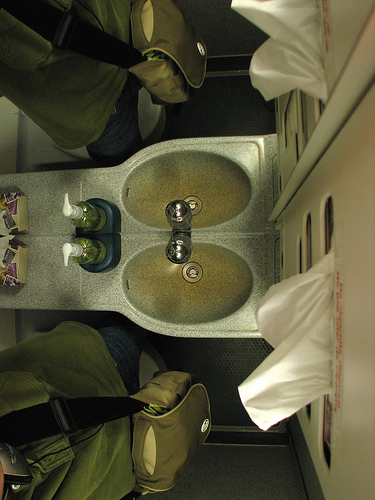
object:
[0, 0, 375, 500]
bathroom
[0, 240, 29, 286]
box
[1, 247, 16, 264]
paper towels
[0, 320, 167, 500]
person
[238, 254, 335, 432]
tissue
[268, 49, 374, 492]
container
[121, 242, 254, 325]
sink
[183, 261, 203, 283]
drain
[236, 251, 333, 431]
towel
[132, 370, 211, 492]
pack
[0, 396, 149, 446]
strap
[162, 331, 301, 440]
floor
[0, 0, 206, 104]
backpack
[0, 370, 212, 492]
backpack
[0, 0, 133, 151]
green shirt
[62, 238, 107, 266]
bottle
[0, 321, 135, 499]
shirt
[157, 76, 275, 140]
floor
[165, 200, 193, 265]
faucet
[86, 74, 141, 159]
jeans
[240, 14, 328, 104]
tissues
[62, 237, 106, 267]
soap bottle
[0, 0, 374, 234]
mirror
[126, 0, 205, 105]
bag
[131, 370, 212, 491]
bag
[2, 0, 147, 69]
strap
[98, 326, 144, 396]
he